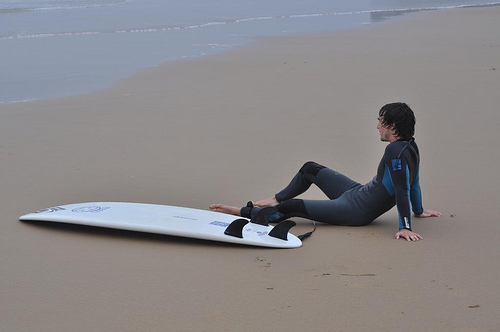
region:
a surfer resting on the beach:
[212, 48, 437, 262]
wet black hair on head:
[383, 105, 408, 135]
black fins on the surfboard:
[229, 212, 306, 241]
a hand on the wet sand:
[396, 225, 419, 246]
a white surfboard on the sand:
[22, 190, 286, 261]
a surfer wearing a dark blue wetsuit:
[262, 77, 431, 234]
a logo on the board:
[77, 199, 104, 216]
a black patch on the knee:
[274, 195, 302, 215]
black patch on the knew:
[301, 157, 325, 179]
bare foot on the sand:
[249, 192, 285, 207]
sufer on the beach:
[203, 101, 488, 236]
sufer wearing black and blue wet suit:
[224, 80, 451, 257]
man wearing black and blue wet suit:
[226, 72, 453, 243]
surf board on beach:
[11, 204, 320, 264]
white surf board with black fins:
[21, 198, 305, 249]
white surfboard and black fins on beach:
[13, 203, 304, 258]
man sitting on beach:
[247, 72, 462, 257]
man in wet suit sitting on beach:
[248, 88, 466, 242]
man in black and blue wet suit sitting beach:
[238, 81, 443, 237]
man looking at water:
[240, 98, 442, 239]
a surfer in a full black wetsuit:
[223, 101, 430, 224]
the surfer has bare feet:
[201, 188, 279, 225]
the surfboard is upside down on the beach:
[20, 193, 304, 250]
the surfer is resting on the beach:
[204, 100, 448, 248]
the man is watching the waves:
[213, 99, 443, 258]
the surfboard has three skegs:
[219, 205, 300, 250]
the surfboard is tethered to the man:
[239, 198, 323, 243]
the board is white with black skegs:
[22, 194, 302, 257]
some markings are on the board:
[28, 200, 269, 242]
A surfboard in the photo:
[10, 190, 180, 237]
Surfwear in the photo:
[242, 130, 439, 248]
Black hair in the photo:
[380, 95, 426, 144]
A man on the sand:
[257, 102, 479, 233]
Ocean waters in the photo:
[49, 25, 157, 66]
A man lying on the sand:
[228, 67, 448, 249]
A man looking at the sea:
[197, 93, 447, 239]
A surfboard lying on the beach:
[32, 175, 330, 270]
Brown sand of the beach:
[111, 250, 376, 310]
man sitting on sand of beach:
[14, 75, 446, 258]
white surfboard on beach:
[19, 188, 305, 270]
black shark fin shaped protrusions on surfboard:
[217, 209, 299, 244]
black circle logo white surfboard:
[67, 201, 113, 214]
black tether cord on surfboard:
[297, 220, 319, 246]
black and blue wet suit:
[242, 139, 431, 229]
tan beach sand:
[5, 0, 498, 330]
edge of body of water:
[2, 1, 496, 111]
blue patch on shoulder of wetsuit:
[387, 157, 403, 173]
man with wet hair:
[362, 99, 421, 141]